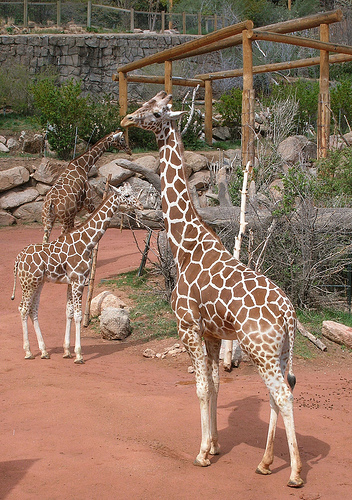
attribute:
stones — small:
[96, 307, 131, 344]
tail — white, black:
[279, 297, 305, 393]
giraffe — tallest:
[114, 83, 317, 476]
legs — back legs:
[254, 350, 303, 489]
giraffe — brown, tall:
[117, 91, 304, 487]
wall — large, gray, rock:
[3, 30, 254, 106]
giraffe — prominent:
[93, 106, 267, 418]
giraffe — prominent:
[119, 89, 330, 493]